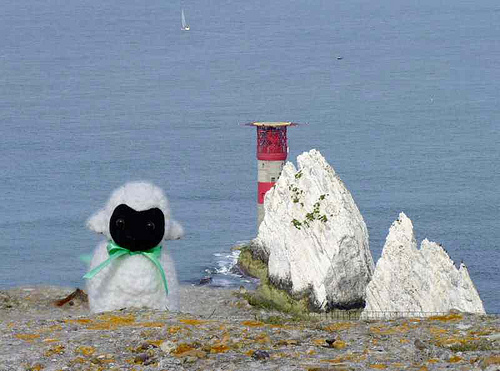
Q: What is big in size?
A: The rock.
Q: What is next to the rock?
A: Stuffed sheep.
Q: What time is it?
A: Afternoon.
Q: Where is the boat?
A: In the water.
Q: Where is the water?
A: Behind the rock.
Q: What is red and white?
A: The pole.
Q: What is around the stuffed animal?
A: A green tie.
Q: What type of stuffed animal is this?
A: Sheep.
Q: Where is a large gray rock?
A: Right of stuffed animal.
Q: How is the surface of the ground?
A: Rocky.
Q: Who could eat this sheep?
A: No living beings.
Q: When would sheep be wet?
A: High tide.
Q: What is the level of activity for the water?
A: Calm.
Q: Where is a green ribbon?
A: Around stuffed animal's neck.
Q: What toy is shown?
A: A sheep.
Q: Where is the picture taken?
A: Seaside.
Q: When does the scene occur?
A: Daytime.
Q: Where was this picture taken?
A: Near the water.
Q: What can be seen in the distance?
A: A sailboat.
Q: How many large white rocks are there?
A: Two.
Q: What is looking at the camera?
A: A stuffed animal.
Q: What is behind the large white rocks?
A: A red and white tower.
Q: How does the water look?
A: Calm.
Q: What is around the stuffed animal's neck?
A: A green ribbon.